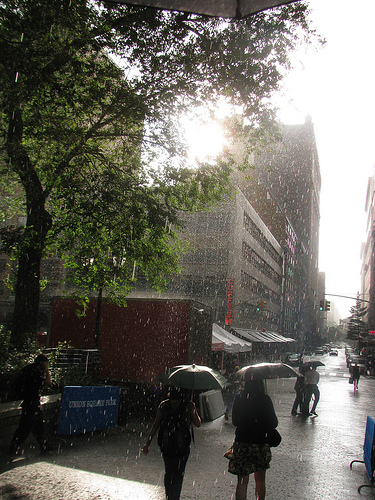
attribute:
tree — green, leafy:
[2, 19, 255, 353]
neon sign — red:
[224, 272, 236, 325]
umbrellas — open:
[154, 360, 302, 401]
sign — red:
[68, 256, 248, 391]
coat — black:
[229, 391, 280, 443]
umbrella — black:
[164, 361, 234, 398]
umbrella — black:
[228, 361, 303, 394]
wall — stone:
[1, 394, 74, 464]